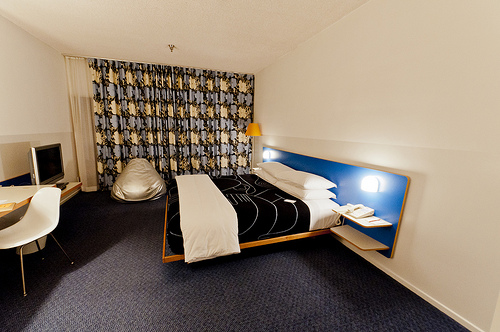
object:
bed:
[161, 144, 411, 263]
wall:
[255, 1, 498, 331]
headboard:
[261, 144, 413, 258]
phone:
[334, 203, 374, 226]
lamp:
[244, 122, 263, 170]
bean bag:
[112, 157, 168, 201]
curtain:
[87, 60, 258, 188]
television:
[32, 143, 66, 188]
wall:
[2, 16, 85, 185]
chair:
[0, 187, 74, 296]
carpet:
[1, 194, 464, 331]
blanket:
[175, 173, 240, 262]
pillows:
[277, 171, 338, 190]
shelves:
[331, 225, 390, 251]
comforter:
[166, 175, 309, 249]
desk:
[0, 181, 79, 228]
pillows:
[258, 160, 295, 178]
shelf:
[333, 204, 393, 228]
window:
[66, 54, 257, 191]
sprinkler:
[167, 43, 177, 53]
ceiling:
[0, 1, 358, 69]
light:
[360, 174, 388, 193]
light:
[262, 148, 281, 159]